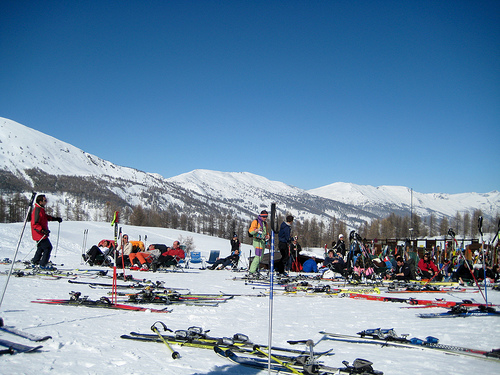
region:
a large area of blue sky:
[0, 0, 499, 195]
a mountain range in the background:
[0, 115, 499, 236]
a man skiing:
[29, 193, 57, 271]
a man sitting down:
[151, 240, 185, 271]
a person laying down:
[127, 243, 161, 270]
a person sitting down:
[114, 233, 131, 268]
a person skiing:
[247, 209, 269, 278]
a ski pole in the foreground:
[266, 201, 276, 373]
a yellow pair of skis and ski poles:
[119, 320, 334, 374]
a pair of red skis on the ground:
[30, 290, 174, 314]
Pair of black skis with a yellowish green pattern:
[125, 314, 235, 356]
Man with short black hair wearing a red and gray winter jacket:
[23, 191, 54, 239]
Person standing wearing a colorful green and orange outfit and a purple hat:
[243, 205, 273, 280]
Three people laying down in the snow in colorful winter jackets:
[99, 234, 184, 269]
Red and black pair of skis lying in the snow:
[344, 286, 457, 311]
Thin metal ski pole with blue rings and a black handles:
[258, 201, 282, 372]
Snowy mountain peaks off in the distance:
[133, 157, 455, 202]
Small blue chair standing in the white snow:
[183, 250, 211, 270]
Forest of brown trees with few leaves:
[367, 212, 497, 232]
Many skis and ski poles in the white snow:
[60, 280, 498, 372]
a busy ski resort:
[21, 131, 497, 353]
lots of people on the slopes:
[199, 181, 497, 313]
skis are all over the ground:
[26, 264, 471, 358]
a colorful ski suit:
[240, 203, 268, 273]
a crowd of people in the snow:
[319, 224, 484, 279]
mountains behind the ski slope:
[4, 115, 486, 244]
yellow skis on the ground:
[140, 308, 332, 374]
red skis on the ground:
[345, 287, 477, 318]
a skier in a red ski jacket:
[25, 191, 66, 265]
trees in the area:
[294, 206, 493, 246]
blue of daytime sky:
[0, 2, 496, 114]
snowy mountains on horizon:
[4, 115, 494, 230]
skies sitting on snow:
[4, 281, 491, 373]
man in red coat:
[29, 193, 61, 270]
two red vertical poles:
[109, 211, 123, 308]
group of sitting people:
[309, 241, 493, 289]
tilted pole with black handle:
[3, 192, 37, 310]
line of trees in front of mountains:
[133, 210, 487, 247]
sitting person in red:
[417, 251, 442, 280]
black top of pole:
[263, 200, 281, 371]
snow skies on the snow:
[0, 278, 498, 373]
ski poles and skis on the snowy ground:
[2, 279, 499, 373]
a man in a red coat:
[28, 193, 63, 273]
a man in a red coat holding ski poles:
[16, 193, 64, 273]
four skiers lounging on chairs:
[81, 232, 186, 274]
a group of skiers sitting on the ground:
[322, 245, 497, 286]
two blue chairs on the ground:
[186, 248, 219, 264]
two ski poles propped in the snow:
[446, 213, 491, 303]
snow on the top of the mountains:
[0, 115, 497, 212]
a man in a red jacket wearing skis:
[12, 192, 63, 276]